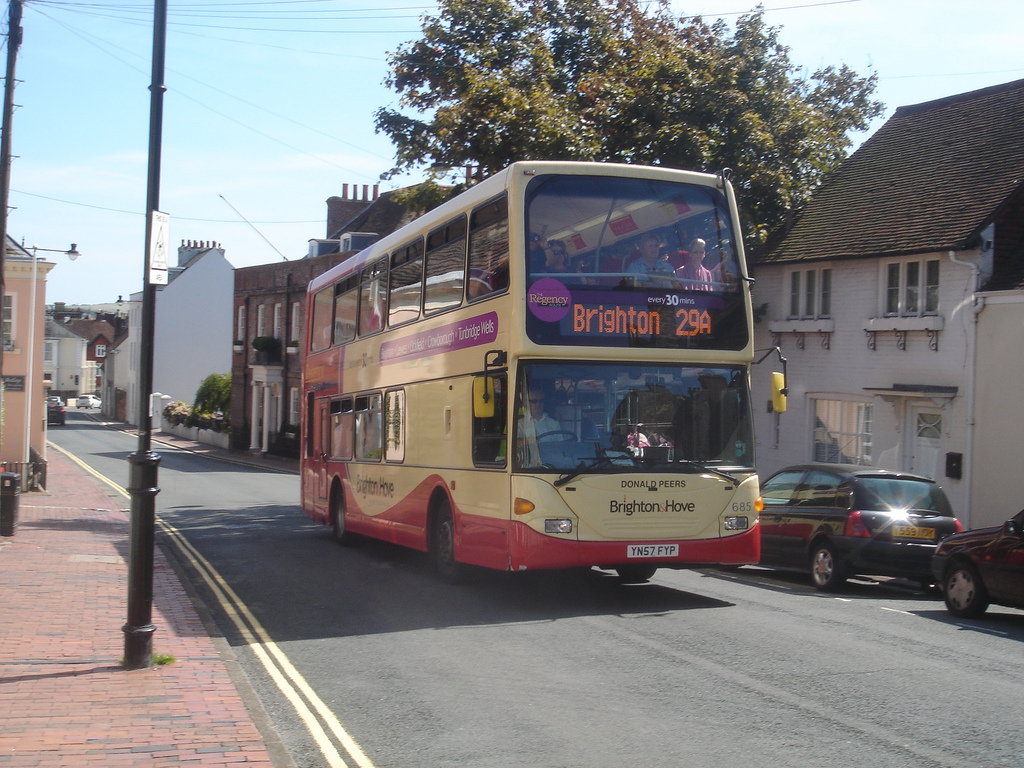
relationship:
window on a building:
[901, 259, 918, 321] [774, 95, 1009, 469]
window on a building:
[812, 392, 889, 473] [752, 79, 1006, 541]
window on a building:
[904, 395, 943, 435] [749, 63, 1021, 588]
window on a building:
[261, 294, 285, 345] [229, 240, 359, 509]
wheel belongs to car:
[805, 544, 845, 595] [745, 436, 976, 596]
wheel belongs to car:
[934, 556, 995, 624] [926, 506, 1022, 624]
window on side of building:
[781, 266, 819, 330] [738, 86, 986, 524]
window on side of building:
[787, 270, 804, 320] [746, 105, 1019, 510]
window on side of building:
[817, 265, 836, 321] [752, 79, 1006, 541]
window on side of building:
[879, 260, 896, 317] [765, 77, 1003, 466]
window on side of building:
[901, 259, 924, 317] [774, 95, 1009, 469]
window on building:
[817, 265, 836, 321] [789, 171, 923, 517]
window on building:
[817, 265, 836, 321] [749, 171, 979, 517]